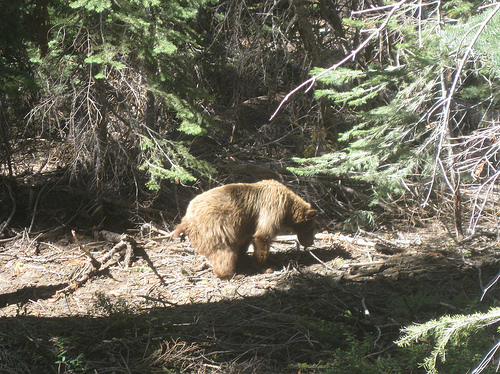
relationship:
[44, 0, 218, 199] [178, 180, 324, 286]
tree by bear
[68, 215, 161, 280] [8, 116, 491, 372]
log on ground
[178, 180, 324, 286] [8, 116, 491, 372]
bear looking at ground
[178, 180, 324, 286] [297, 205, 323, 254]
bear has bowed head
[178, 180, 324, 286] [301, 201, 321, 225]
bear has ears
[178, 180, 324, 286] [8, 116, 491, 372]
bear preparing to sit on ground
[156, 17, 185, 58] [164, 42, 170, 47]
leaves in a cluster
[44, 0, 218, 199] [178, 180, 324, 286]
tree behind bear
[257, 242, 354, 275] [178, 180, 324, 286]
shadow from bear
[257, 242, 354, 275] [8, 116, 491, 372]
shadow on ground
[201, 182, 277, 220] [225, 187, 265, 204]
back has a hump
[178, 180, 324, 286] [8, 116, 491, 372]
bear on ground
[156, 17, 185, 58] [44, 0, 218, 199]
leaves to pine tree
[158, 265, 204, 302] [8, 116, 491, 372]
needles on ground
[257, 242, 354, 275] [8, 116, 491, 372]
shadow cast on ground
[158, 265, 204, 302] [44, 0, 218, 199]
needles on tree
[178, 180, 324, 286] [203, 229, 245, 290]
bear has legs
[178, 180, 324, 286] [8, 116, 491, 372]
bear looking toward ground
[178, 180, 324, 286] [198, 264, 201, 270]
bear preparing to sit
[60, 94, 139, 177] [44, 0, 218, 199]
limbs on tree